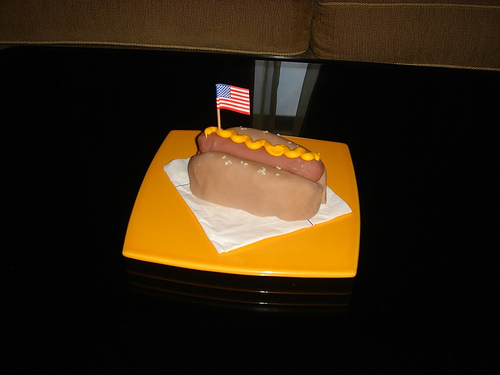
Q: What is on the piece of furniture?
A: The brown cushion.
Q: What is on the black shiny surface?
A: The plate.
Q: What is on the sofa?
A: The brown cushion.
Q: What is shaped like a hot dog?
A: The cake.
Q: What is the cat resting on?
A: The white napkin.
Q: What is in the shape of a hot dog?
A: The dessert.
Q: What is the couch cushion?
A: The seat.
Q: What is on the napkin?
A: Food.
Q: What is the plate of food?
A: Orange.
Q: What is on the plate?
A: Hotdog.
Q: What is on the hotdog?
A: Tiny American flag.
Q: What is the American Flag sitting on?
A: A hotdog.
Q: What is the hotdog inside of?
A: A bun.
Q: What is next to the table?
A: A couch.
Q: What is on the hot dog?
A: The American flag.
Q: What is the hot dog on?
A: A yellow plate.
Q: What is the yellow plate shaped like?
A: Square.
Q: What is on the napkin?
A: A yellow plate.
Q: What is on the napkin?
A: A hot dog.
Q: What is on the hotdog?
A: A flag.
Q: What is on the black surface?
A: The yellow plate.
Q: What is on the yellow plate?
A: A fake hot dog.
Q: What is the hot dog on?
A: A yellow square plate.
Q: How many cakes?
A: 1.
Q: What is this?
A: A hot dog cake.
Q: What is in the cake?
A: A flag.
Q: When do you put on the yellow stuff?
A: Last.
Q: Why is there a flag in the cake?
A: Decoration.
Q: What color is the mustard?
A: Yellow.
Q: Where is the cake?
A: On a yellow plate.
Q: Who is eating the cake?
A: Nobody.